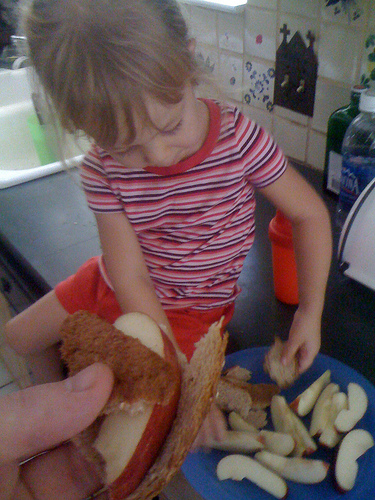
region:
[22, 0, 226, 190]
the hair is blonde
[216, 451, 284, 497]
slice of an apple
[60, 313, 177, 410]
a piece of chicken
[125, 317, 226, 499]
a piece of bread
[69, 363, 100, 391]
thumb nail of a person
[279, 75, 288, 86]
switch on the wall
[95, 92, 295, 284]
red and white shirt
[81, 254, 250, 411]
girl has red shorts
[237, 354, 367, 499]
apple has been sliced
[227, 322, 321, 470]
apples on blue plate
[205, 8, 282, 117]
white floral pattern on wall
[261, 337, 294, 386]
BOY HOLDING A PIECE OF BREAD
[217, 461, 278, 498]
SLICE APPLE ON PLATE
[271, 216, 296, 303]
RED CUP ON THE TABLE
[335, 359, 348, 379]
BLUE PLATE ON THE TABLE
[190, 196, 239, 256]
BOY WEARING A STRIPE SHIRT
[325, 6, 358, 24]
PRINT ON THE TILE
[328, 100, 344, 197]
GREEN BOTTLE ON THE TABLE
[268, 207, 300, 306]
Orange plastic sippy cup.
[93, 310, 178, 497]
Apple slice with red skin in a persons hand.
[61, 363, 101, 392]
Very upclose thumb nail.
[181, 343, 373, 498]
Round blue plate.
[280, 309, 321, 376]
Child's left hand holding bread.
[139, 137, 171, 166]
Nose of a small girl.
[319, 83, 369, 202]
Green bottle of Jagermeister on the counter.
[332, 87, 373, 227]
A clear plastic bottle with blue label and white lid.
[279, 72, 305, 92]
Two cream light switches.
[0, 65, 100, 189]
A double white sink.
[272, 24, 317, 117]
dark brown light swich on wall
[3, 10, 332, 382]
little girl sitting on a counter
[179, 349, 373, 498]
a round blue plate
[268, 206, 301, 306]
an orange sippy cup on the counter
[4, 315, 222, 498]
a hand holding a piece of apple and bread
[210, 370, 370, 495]
apple slices on the plate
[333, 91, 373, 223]
a plastic water bottle on the counter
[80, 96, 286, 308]
the girl's striped stirt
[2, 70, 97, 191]
a white sink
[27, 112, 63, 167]
a green plastic cup in the sink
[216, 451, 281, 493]
apple slice on plate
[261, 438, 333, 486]
apple slice on plate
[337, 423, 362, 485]
apple slice on plate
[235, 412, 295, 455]
apple slice on plate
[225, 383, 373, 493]
slices of apples on a dish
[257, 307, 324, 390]
hand holding a piece of bread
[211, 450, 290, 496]
a slice of apple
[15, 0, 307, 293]
the toddler is blonde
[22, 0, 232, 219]
the toddler is eating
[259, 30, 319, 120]
light switch on the wall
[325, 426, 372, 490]
slice of apple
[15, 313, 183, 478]
hand holding an apple